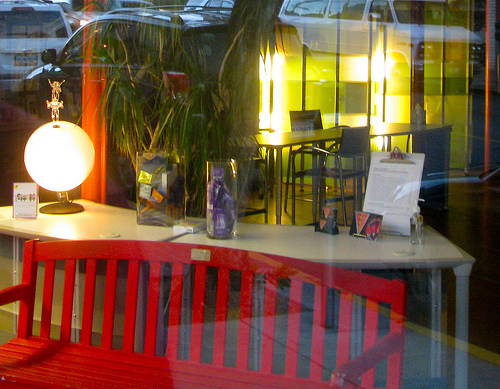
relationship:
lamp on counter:
[18, 116, 107, 193] [0, 152, 467, 305]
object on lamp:
[44, 74, 69, 119] [18, 79, 96, 212]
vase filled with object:
[128, 139, 188, 224] [130, 147, 177, 228]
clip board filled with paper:
[360, 146, 426, 235] [370, 150, 412, 234]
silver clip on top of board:
[384, 148, 421, 173] [362, 136, 433, 219]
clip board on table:
[360, 146, 426, 235] [0, 186, 470, 386]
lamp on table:
[23, 119, 95, 194] [0, 186, 470, 386]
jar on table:
[203, 163, 239, 243] [0, 186, 470, 386]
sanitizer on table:
[410, 196, 425, 246] [0, 186, 470, 386]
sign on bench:
[189, 240, 210, 267] [2, 217, 407, 387]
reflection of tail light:
[17, 7, 302, 174] [158, 67, 196, 117]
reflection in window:
[17, 7, 302, 174] [4, 4, 498, 379]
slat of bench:
[26, 254, 61, 340] [2, 217, 407, 387]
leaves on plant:
[157, 103, 188, 137] [91, 2, 279, 204]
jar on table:
[205, 158, 239, 239] [4, 156, 472, 288]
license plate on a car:
[15, 50, 41, 70] [0, 0, 70, 95]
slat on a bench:
[143, 260, 168, 356] [2, 217, 407, 387]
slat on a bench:
[165, 264, 183, 357] [1, 238, 407, 383]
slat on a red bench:
[235, 269, 255, 369] [1, 239, 408, 387]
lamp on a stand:
[23, 119, 95, 194] [39, 196, 87, 213]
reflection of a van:
[276, 0, 483, 97] [2, 3, 75, 96]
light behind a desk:
[260, 44, 399, 151] [254, 120, 454, 223]